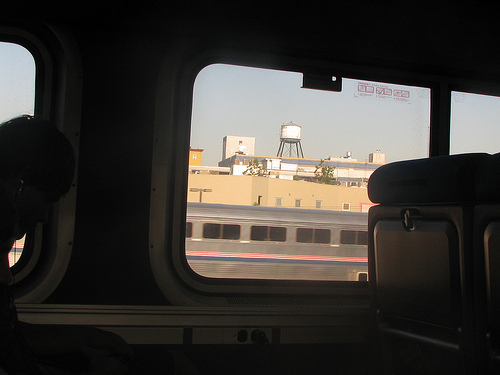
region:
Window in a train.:
[162, 45, 444, 297]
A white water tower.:
[279, 118, 302, 158]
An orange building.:
[184, 140, 206, 175]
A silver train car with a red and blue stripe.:
[183, 202, 368, 279]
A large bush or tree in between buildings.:
[310, 155, 340, 187]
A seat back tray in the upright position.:
[360, 200, 470, 341]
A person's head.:
[2, 110, 74, 240]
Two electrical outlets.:
[232, 322, 269, 347]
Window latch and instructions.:
[304, 69, 418, 101]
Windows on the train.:
[204, 221, 330, 244]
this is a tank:
[278, 119, 308, 144]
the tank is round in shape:
[273, 122, 308, 144]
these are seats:
[373, 170, 499, 364]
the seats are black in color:
[370, 158, 472, 364]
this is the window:
[176, 56, 374, 276]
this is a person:
[6, 120, 108, 370]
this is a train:
[209, 204, 354, 273]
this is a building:
[226, 178, 346, 211]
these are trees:
[240, 157, 341, 182]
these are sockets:
[222, 326, 273, 348]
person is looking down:
[0, 113, 206, 373]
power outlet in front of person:
[236, 327, 268, 343]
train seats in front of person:
[367, 151, 499, 373]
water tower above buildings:
[276, 120, 305, 157]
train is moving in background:
[8, 202, 368, 282]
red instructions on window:
[356, 80, 411, 100]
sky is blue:
[0, 41, 499, 167]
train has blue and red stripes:
[9, 244, 368, 266]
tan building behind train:
[186, 172, 379, 212]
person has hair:
[0, 114, 77, 196]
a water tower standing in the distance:
[271, 116, 317, 154]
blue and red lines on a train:
[216, 246, 332, 271]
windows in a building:
[273, 189, 351, 214]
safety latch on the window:
[239, 329, 289, 350]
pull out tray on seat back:
[364, 214, 456, 324]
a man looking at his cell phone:
[10, 112, 137, 365]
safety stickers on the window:
[353, 78, 416, 106]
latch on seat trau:
[401, 206, 417, 231]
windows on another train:
[246, 219, 338, 250]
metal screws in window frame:
[144, 179, 153, 266]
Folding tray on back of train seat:
[370, 209, 473, 353]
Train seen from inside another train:
[165, 188, 365, 287]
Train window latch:
[187, 43, 440, 110]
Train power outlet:
[222, 325, 276, 349]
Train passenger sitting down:
[0, 107, 145, 367]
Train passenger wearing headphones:
[7, 160, 33, 228]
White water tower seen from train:
[276, 118, 306, 163]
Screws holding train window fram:
[145, 71, 169, 268]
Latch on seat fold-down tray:
[398, 208, 418, 230]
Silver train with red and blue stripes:
[220, 242, 318, 268]